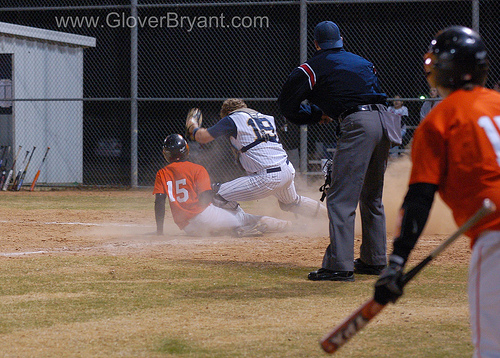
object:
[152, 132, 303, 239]
player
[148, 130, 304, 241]
man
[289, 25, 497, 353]
man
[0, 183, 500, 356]
field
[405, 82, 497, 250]
shirt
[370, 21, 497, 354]
player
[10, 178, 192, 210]
grass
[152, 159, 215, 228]
shirt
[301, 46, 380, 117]
shirt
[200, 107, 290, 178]
shirt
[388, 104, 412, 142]
shirt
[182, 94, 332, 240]
catcher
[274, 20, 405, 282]
umpire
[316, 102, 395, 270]
pants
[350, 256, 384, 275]
shoes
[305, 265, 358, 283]
shoes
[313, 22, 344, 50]
cap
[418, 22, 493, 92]
helmet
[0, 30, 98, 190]
wall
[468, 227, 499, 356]
white pants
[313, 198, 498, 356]
bat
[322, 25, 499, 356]
batter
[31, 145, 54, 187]
racket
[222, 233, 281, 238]
home plate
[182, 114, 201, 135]
glove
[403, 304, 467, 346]
deck circle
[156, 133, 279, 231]
runner